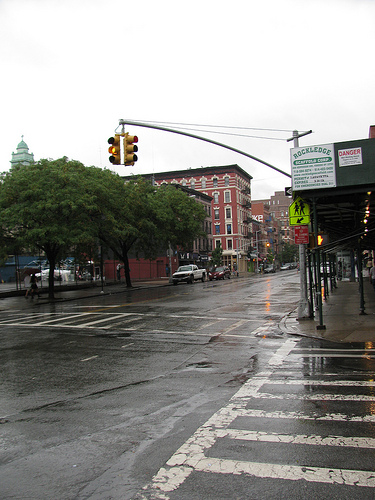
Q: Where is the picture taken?
A: A street corner.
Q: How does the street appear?
A: Wet.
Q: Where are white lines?
A: On the street.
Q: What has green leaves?
A: Two trees.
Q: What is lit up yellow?
A: Traffic light on left.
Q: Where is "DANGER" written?
A: On white sign on the right.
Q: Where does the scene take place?
A: Near city street.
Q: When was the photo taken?
A: During daytime.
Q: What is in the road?
A: Pole.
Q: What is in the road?
A: Signs.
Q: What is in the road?
A: Building.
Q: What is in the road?
A: Trees.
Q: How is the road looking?
A: Watery.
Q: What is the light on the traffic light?
A: Amber.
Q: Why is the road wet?
A: It has just rained.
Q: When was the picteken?
A: During the day.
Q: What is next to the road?
A: Trees.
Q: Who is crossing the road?
A: A woman with an umbrella.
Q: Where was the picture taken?
A: On a wet street.